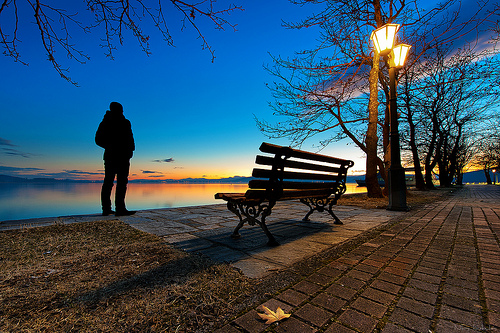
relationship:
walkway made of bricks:
[231, 183, 496, 329] [381, 263, 452, 320]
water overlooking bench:
[0, 127, 390, 209] [206, 145, 420, 276]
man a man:
[93, 101, 136, 216] [93, 101, 136, 216]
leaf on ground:
[255, 304, 292, 326] [1, 179, 499, 331]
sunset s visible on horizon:
[145, 163, 235, 185] [5, 58, 498, 202]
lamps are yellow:
[338, 17, 430, 104] [341, 49, 449, 229]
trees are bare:
[246, 2, 498, 173] [332, 55, 456, 206]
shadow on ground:
[169, 218, 329, 275] [117, 198, 375, 308]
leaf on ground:
[255, 302, 289, 326] [210, 287, 248, 327]